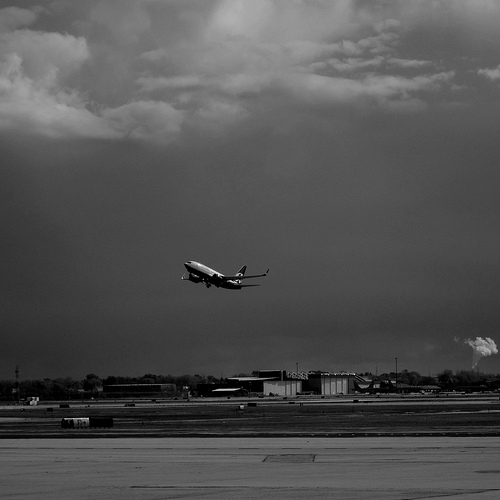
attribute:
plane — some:
[179, 257, 272, 293]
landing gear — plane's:
[202, 280, 211, 289]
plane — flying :
[179, 244, 286, 309]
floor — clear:
[1, 393, 498, 498]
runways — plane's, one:
[1, 438, 498, 497]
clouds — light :
[161, 0, 441, 136]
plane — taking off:
[148, 248, 271, 313]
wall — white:
[319, 371, 358, 402]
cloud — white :
[393, 0, 498, 72]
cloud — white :
[136, 3, 461, 118]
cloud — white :
[470, 68, 498, 81]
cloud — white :
[0, 1, 42, 30]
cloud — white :
[1, 28, 248, 148]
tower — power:
[4, 360, 29, 387]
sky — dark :
[1, 2, 495, 376]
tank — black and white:
[61, 416, 115, 430]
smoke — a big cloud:
[443, 335, 498, 353]